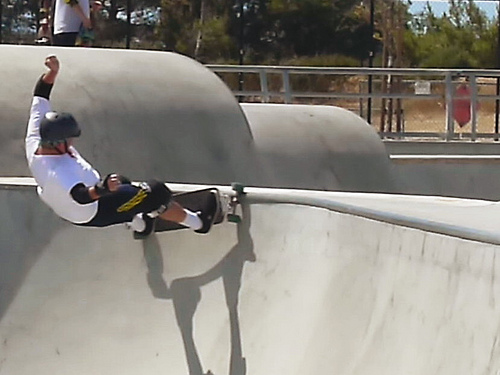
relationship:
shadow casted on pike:
[140, 200, 258, 372] [1, 173, 484, 373]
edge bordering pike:
[1, 181, 484, 243] [1, 173, 484, 373]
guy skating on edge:
[24, 54, 220, 237] [1, 181, 484, 243]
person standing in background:
[50, 0, 101, 46] [1, 0, 484, 139]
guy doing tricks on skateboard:
[24, 54, 220, 237] [147, 181, 248, 234]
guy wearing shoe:
[24, 54, 220, 237] [131, 209, 158, 242]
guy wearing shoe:
[24, 54, 220, 237] [194, 183, 221, 234]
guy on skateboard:
[24, 54, 220, 237] [134, 180, 248, 231]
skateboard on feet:
[147, 181, 248, 234] [129, 190, 220, 234]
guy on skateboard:
[24, 54, 220, 237] [150, 180, 249, 230]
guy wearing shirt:
[9, 50, 234, 232] [22, 103, 92, 223]